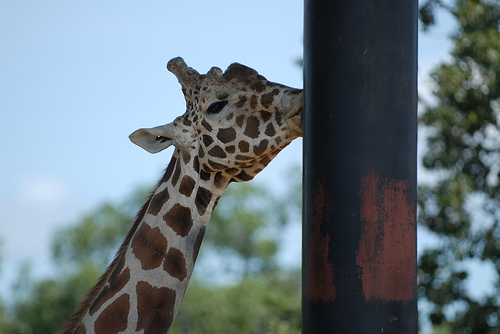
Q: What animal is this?
A: Giraffe.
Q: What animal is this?
A: Giraffe.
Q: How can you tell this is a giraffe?
A: Face, spots, neck.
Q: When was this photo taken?
A: Daylight hours.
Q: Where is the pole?
A: Next to the giraffe.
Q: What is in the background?
A: Trees.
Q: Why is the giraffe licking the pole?
A: Mistaking tree for pole.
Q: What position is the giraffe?
A: Standing up.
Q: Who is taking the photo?
A: Photographer is not in image.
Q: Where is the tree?
A: In the distant background.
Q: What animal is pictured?
A: Giraffe.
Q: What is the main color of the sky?
A: Blue.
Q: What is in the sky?
A: Cloud.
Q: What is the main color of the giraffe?
A: Brown and white.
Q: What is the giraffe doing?
A: Kissing the pole.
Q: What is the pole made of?
A: Metal.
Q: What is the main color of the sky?
A: Blue.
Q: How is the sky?
A: Clear.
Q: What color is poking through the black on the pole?
A: Red.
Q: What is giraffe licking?
A: Pole.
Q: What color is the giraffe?
A: Brown and tan.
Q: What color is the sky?
A: Blue.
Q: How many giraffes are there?
A: One.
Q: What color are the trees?
A: Green.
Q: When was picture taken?
A: Daytime.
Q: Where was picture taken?
A: At a zoo.